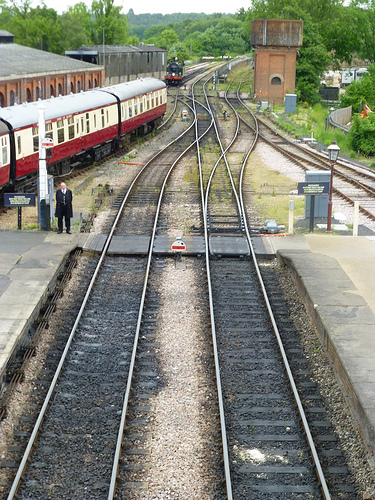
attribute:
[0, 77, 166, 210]
train — white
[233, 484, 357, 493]
plank — black, wooden, small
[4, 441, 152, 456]
plank — small, wooden, black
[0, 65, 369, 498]
gravel — black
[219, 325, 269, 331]
wood plank — small, black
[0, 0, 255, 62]
trees — green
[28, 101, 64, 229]
pole — white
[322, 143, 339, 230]
post — narrow, brown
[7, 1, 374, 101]
trees — green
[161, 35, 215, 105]
train — red, black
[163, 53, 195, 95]
train engine — black, red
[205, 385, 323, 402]
wood plank — small, black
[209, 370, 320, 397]
wood plank — black, small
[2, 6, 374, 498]
railroad station — rural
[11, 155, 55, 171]
trim — red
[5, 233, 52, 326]
train platform — grey